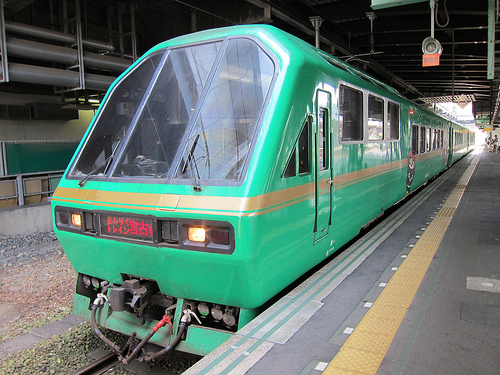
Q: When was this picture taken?
A: Daytime.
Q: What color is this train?
A: Green.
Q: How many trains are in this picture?
A: 1.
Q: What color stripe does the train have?
A: Gold.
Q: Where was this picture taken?
A: Train station.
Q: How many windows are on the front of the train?
A: 3.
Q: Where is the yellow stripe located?
A: Train platform.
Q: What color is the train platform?
A: Grey.